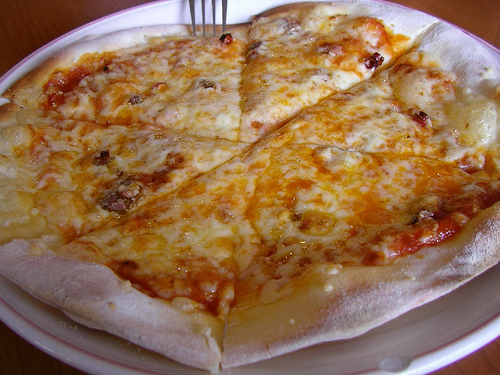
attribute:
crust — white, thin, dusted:
[6, 244, 206, 350]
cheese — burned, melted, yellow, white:
[90, 93, 263, 211]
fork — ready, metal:
[184, 0, 228, 42]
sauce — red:
[397, 209, 459, 253]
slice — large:
[19, 8, 254, 144]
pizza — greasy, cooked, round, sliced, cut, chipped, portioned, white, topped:
[3, 2, 500, 369]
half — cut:
[10, 108, 493, 321]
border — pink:
[6, 11, 171, 69]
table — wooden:
[0, 11, 489, 76]